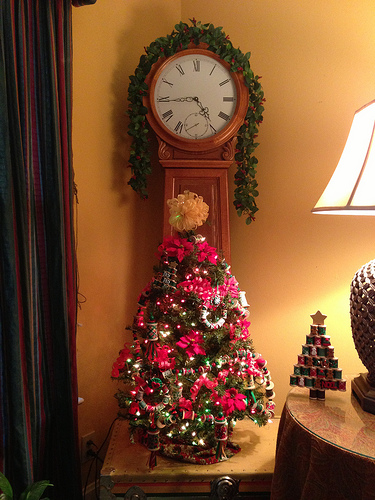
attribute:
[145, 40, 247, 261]
clock — grandfather clock, decorated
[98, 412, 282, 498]
trunk — brown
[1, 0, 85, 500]
curtains — striped, multi-colored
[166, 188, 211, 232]
bow — beige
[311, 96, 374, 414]
lamp — brown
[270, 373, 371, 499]
table — small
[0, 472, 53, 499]
leaves — green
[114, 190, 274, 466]
christmas tree — small, decorated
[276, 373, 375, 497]
table cloth — red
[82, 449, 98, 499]
cord — black